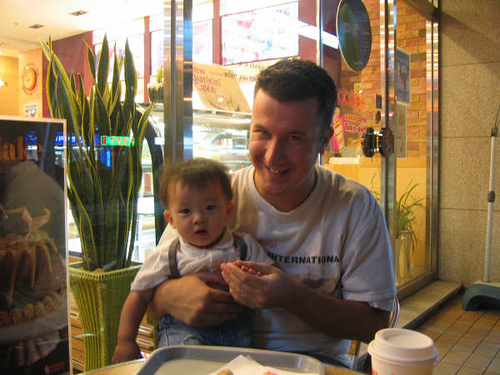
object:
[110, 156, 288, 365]
boy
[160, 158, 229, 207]
hair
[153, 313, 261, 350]
jeans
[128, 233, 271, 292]
shirt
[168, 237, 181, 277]
suspenders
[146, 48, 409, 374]
man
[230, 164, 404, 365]
shirt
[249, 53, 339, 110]
hair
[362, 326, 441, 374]
coffe cup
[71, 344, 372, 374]
table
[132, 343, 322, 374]
tray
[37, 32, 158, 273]
plant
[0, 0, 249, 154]
background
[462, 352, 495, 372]
tiles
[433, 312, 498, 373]
ground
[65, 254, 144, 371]
vase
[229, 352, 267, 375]
napkin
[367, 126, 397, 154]
lock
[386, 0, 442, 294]
door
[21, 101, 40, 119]
picture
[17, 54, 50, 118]
wall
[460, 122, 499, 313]
scraper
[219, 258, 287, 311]
hand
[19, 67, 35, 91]
clock